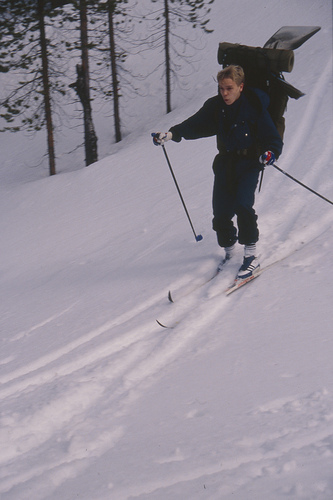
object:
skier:
[151, 63, 283, 278]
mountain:
[0, 0, 329, 500]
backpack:
[217, 26, 321, 143]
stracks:
[86, 176, 328, 499]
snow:
[10, 292, 330, 499]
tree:
[136, 0, 217, 112]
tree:
[94, 0, 147, 142]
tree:
[48, 0, 109, 168]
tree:
[0, 0, 64, 176]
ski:
[156, 260, 283, 330]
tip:
[155, 319, 167, 329]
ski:
[167, 258, 219, 305]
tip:
[167, 289, 174, 303]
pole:
[270, 163, 333, 207]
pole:
[161, 143, 204, 241]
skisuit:
[168, 89, 284, 246]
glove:
[259, 150, 275, 166]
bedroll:
[217, 42, 294, 73]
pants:
[211, 173, 259, 245]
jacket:
[169, 88, 283, 177]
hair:
[217, 64, 245, 87]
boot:
[237, 256, 261, 280]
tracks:
[0, 68, 331, 500]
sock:
[243, 243, 254, 259]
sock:
[225, 245, 236, 257]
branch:
[0, 76, 40, 109]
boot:
[217, 253, 232, 271]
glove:
[151, 132, 171, 146]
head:
[218, 67, 244, 105]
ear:
[239, 82, 244, 91]